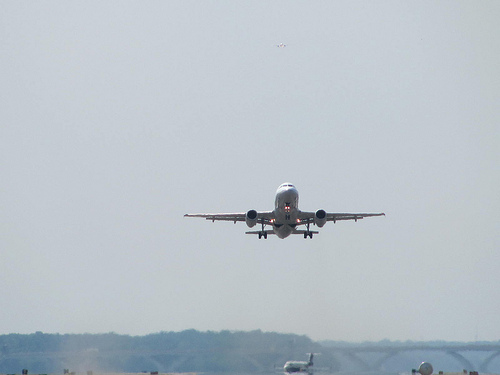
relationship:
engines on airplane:
[242, 205, 331, 232] [177, 177, 389, 244]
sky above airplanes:
[3, 3, 495, 336] [185, 174, 394, 252]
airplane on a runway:
[105, 174, 452, 312] [156, 370, 446, 372]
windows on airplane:
[275, 181, 297, 191] [167, 168, 407, 278]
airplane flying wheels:
[182, 182, 387, 240] [253, 226, 310, 248]